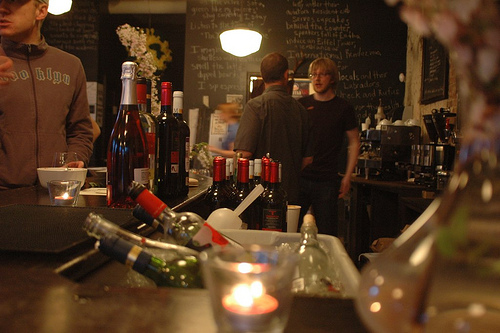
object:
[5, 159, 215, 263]
table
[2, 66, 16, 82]
lettering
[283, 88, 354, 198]
shirt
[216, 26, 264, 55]
light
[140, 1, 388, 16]
ceiling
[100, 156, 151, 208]
liquid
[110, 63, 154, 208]
bottle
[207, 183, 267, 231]
scoop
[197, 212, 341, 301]
ice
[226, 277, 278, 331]
candle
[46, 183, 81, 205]
candle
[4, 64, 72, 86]
brooklyn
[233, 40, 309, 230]
man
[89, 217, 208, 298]
bottle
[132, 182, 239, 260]
bottle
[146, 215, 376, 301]
container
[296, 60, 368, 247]
man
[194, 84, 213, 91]
writing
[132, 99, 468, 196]
background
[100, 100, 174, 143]
top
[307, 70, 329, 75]
glasses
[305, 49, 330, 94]
face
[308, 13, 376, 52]
walls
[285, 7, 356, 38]
chalkboard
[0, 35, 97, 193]
hoodie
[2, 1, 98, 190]
customer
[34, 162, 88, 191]
bowl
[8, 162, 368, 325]
bar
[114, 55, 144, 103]
top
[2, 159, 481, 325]
bar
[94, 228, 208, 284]
bottle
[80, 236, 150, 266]
top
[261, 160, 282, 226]
bottles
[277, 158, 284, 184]
tops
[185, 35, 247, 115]
chalkboard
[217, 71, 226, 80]
writing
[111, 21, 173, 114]
bouquet